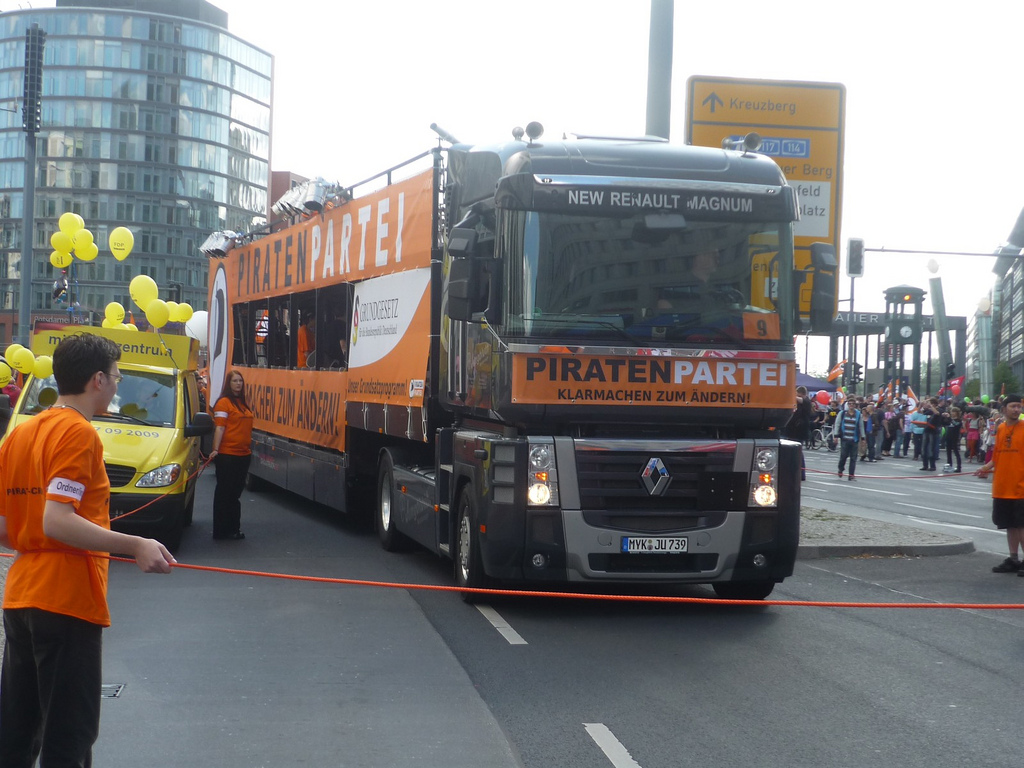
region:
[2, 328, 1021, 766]
People holding orange rope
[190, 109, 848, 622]
Big black and orange truck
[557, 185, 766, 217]
Words printed on top of the bus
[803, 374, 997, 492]
People standing on the road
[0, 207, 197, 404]
Yellow balloons in the air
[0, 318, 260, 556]
Woman next to a yellow vehicle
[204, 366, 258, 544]
Woman in black pants wearing orange shirt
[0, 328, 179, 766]
Guy in orange shirt wearing black pants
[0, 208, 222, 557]
Yellow vehicle with lots of yelllow balloons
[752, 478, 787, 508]
a headlight on the bus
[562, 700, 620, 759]
a white line in the street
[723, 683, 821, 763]
the street is grey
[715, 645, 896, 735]
the street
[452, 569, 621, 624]
an orange rope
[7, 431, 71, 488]
an orange shirt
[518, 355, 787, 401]
a banner on the bus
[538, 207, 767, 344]
a windshield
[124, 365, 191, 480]
a van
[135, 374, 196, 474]
the van is yellow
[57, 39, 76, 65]
a window on a building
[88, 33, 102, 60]
a window on a building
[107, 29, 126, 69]
a window on a building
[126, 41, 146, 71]
a window on a building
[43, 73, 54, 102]
a window on a building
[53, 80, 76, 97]
a window on a building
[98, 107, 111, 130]
a window on a building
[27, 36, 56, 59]
glass window on the building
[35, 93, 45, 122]
glass window on the building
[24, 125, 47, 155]
glass window on the building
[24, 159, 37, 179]
glass window on the building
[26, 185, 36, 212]
glass window on the building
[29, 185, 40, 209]
glass window on the building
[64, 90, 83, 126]
glass window on the building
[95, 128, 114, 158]
glass window on the building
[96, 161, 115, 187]
glass window on the building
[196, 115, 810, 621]
orange and black truck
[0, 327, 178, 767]
man wearing orange shirt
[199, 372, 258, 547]
woman wearing orange shirt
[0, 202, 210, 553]
yellow balloons above yellow van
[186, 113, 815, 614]
black truck with headlights on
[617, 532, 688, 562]
white license plate with black writing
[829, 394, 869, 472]
person wearing blue and white striped shirt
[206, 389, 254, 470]
woman wearing a orange shirt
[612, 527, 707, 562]
license plate on the truck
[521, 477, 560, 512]
head light on the truck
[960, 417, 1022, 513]
man wearing a orange shirt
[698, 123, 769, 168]
horn on top of truck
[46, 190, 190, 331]
yellow balloons over the van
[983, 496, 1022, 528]
man wearing black shorts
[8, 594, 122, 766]
man wearing black pants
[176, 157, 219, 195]
a window onthe building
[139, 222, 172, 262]
a window onthe building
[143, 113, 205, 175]
a window onthe building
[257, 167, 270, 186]
a window onthe building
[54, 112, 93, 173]
a window onthe building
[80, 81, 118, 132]
a window onthe building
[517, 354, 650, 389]
The word 'pirate' on the bus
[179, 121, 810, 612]
Large orange and black bus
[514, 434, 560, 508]
Headlight of a bus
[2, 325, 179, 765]
Man in an orange shirt